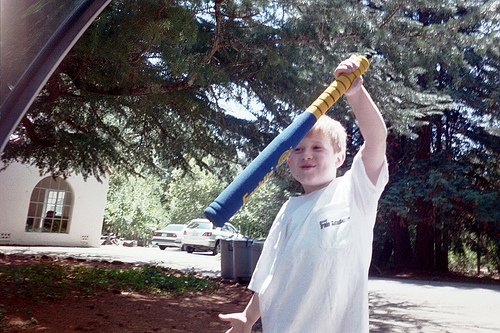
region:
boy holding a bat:
[155, 18, 409, 328]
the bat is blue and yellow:
[135, 28, 425, 278]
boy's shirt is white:
[223, 187, 366, 326]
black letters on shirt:
[308, 199, 360, 248]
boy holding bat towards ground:
[162, 50, 443, 275]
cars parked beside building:
[130, 158, 240, 270]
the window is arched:
[23, 160, 82, 240]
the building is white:
[1, 141, 101, 251]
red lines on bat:
[296, 61, 365, 109]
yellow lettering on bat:
[216, 168, 283, 217]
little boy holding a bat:
[201, 50, 389, 331]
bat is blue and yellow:
[205, 53, 375, 227]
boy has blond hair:
[302, 114, 346, 154]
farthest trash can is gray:
[220, 237, 233, 279]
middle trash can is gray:
[231, 239, 251, 279]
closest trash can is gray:
[252, 238, 263, 271]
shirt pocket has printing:
[311, 200, 352, 252]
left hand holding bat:
[204, 49, 370, 228]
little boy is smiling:
[217, 55, 389, 331]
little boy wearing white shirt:
[216, 54, 389, 331]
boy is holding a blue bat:
[196, 44, 371, 234]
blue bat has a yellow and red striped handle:
[298, 27, 393, 152]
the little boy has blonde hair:
[276, 96, 366, 173]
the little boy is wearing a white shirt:
[202, 155, 371, 330]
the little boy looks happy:
[279, 118, 340, 206]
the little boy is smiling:
[288, 133, 345, 202]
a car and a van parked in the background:
[142, 196, 262, 295]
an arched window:
[10, 163, 102, 255]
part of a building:
[6, 136, 122, 271]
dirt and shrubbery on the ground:
[15, 235, 274, 331]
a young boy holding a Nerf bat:
[218, 51, 390, 331]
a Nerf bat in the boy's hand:
[205, 53, 370, 224]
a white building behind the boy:
[1, 110, 110, 246]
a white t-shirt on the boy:
[246, 140, 389, 331]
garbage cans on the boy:
[219, 236, 264, 281]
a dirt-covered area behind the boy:
[0, 253, 257, 332]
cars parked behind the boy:
[151, 217, 238, 250]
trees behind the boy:
[0, 0, 499, 282]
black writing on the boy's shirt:
[318, 216, 351, 228]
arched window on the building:
[24, 173, 74, 230]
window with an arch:
[26, 169, 80, 244]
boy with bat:
[199, 43, 399, 328]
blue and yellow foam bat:
[193, 52, 368, 229]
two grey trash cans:
[215, 235, 255, 281]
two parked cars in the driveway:
[150, 210, 241, 251]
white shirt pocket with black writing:
[307, 197, 359, 253]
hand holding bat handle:
[326, 50, 371, 98]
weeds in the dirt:
[11, 257, 206, 295]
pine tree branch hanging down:
[391, 71, 453, 146]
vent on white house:
[75, 230, 102, 250]